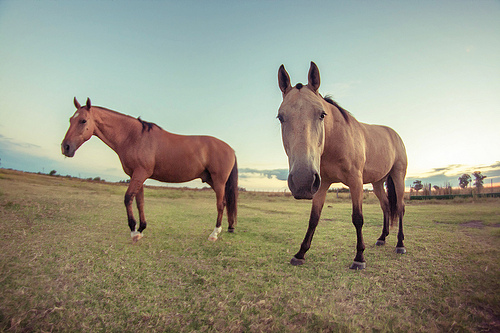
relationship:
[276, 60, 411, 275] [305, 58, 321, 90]
horse has ear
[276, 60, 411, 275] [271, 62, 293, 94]
horse has ear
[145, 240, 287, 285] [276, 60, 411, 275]
grass beneath horse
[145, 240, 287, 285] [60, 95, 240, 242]
grass beneath horse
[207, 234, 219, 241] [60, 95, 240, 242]
hoof of horse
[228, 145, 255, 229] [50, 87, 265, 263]
tail of horse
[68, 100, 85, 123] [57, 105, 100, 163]
blaze on head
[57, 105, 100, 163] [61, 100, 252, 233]
head of horse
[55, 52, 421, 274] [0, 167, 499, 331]
horses in a field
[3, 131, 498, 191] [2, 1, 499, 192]
clouds in sky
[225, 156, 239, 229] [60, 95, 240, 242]
tail of horse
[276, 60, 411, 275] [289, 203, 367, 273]
horse has front legs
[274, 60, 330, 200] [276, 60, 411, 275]
head of horse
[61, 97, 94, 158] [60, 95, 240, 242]
head of horse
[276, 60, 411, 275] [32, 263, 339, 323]
horse in field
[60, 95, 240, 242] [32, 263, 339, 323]
horse in field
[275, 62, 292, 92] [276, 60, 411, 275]
ear of horse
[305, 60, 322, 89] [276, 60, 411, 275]
ear of horse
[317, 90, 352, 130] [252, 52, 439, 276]
mane on horse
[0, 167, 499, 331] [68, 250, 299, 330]
field of grass